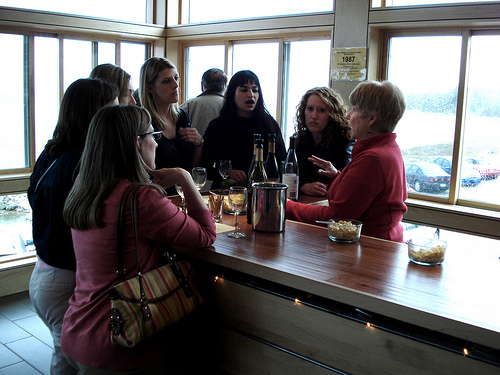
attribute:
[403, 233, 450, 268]
bowl — Clear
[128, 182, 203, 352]
straps — leather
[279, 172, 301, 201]
label — white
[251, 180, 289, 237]
bucket — silver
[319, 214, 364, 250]
bowl — clear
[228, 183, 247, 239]
wine glass — empty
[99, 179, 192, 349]
purse — striped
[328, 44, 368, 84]
sign — yellow, laminated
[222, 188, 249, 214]
bowl — clear